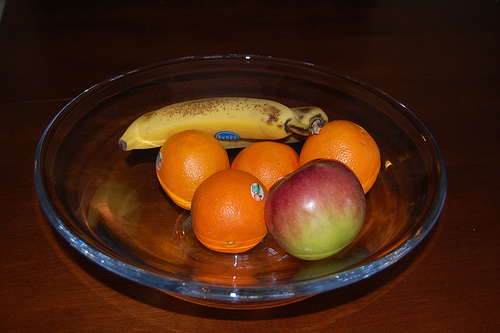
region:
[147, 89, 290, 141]
the banana is ripe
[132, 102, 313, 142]
the banana is yellow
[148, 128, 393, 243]
the oranges are four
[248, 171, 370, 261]
the apple is redand green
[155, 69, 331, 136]
the bananas are two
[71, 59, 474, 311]
the fruits are in a glass plate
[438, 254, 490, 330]
the surface is brown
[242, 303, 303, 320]
shadow is on the table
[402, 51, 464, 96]
the surface is wooden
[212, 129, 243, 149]
sticker is on the banana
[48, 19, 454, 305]
plate on a table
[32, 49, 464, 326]
round plate on a table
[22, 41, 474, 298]
clear plate on a table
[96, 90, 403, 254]
fruits on a plate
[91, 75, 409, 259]
fruits on a clear plate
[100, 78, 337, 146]
banana on a plate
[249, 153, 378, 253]
apple on a plate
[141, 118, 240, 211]
orange on a plate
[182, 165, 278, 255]
orange on a plate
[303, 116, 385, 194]
orange on a plate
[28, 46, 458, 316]
fruit in a glass bowl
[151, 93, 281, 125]
brown dots on the banana peel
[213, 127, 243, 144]
blue sticker on the banana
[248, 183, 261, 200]
small sticker on the orange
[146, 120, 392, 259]
a group of four oranges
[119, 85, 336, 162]
two bananas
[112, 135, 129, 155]
bottom of the banana is black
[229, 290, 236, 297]
small light glare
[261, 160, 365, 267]
red and green apple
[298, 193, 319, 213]
glare on the apple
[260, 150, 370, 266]
piece of fruit in a glass bowl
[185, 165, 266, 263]
piece of fruit in a glass bowl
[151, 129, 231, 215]
piece of fruit in a glass bowl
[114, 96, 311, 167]
piece of fruit in a glass bowl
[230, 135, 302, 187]
piece of fruit in a glass bowl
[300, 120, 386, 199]
piece of fruit in a glass bowl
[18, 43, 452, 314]
large glass bowl with fruit inside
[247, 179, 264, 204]
white sticker on an orange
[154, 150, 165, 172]
white sticker on an orange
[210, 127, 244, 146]
blue sticker on a banana